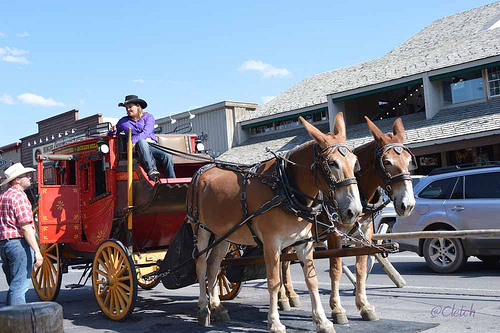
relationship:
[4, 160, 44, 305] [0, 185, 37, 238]
person with plaid shirt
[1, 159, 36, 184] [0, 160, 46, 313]
cowboy hat hat on person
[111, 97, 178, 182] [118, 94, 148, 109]
man has hat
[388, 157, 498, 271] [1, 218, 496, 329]
car on street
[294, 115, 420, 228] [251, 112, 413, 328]
heads of horse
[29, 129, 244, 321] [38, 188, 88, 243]
carriage has designs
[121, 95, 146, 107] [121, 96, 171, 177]
hat on man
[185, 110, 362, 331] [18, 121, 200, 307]
horse pulling stagecoach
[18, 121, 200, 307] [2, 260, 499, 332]
stagecoach down a street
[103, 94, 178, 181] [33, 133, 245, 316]
man on a stage coach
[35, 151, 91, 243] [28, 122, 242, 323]
door on a stagecoach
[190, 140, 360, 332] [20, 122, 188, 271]
horse pulling stagecoach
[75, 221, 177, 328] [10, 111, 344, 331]
wheel of stagecoach